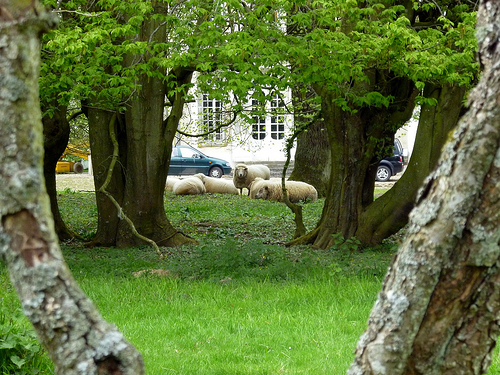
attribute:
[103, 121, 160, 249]
trunk — tree, large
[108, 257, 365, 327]
grass — tall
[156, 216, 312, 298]
grass — shady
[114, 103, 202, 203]
trunk — tree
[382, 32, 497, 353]
tree — old, peeled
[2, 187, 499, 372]
grass — short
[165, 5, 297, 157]
building — beige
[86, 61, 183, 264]
trunk — large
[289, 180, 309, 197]
wool — white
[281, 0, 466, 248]
tree — leaves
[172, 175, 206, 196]
sheep — white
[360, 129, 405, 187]
car — black, back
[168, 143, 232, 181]
car — green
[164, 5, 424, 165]
building — white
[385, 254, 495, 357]
trunk — tree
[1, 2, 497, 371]
park — city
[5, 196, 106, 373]
tree — skinny, small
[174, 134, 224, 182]
car — green